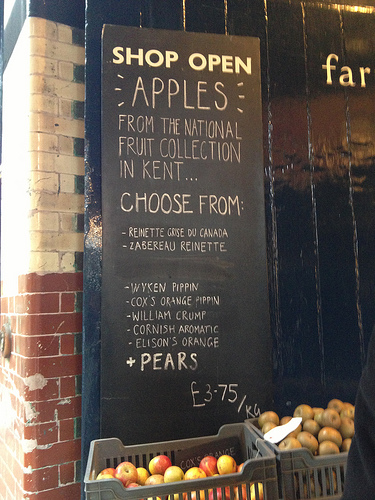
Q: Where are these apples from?
A: Kent.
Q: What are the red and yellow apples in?
A: A crate.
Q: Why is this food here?
A: It is for sale.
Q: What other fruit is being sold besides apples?
A: Pears.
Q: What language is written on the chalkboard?
A: English.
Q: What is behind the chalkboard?
A: Brick wall.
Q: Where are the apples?
A: In a crate.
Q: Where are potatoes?
A: In the crate.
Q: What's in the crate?
A: Potatoes.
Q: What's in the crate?
A: Apples.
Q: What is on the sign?
A: Words.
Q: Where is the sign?
A: On the wall.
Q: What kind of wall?
A: Brick.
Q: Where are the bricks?
A: On the wall.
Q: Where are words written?
A: Sign.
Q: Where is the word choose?
A: On the sign.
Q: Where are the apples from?
A: National fruit collection in Kent.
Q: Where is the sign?
A: On the wall.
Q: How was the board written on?
A: Chalk.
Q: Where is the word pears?
A: Blackboard.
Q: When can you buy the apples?
A: When you have 3.75 pounds.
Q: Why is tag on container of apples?
A: Price tag.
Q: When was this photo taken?
A: During the day.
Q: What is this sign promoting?
A: Apples.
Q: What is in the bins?
A: Apples.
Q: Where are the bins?
A: Under the sign.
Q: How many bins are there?
A: Two.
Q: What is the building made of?
A: Brick.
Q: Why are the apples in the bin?
A: They are for sale.